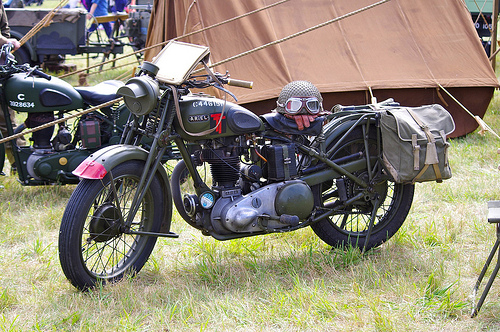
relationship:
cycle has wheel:
[50, 41, 451, 297] [64, 151, 163, 289]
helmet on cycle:
[268, 80, 322, 114] [50, 41, 451, 297]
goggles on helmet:
[282, 89, 321, 116] [268, 80, 322, 114]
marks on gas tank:
[212, 112, 231, 134] [186, 97, 252, 133]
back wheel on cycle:
[312, 120, 411, 252] [50, 41, 451, 297]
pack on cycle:
[382, 108, 452, 181] [50, 41, 451, 297]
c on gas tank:
[191, 101, 198, 110] [186, 97, 252, 133]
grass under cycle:
[156, 254, 326, 331] [50, 41, 451, 297]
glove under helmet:
[291, 114, 317, 124] [268, 80, 322, 114]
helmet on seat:
[268, 80, 322, 114] [263, 116, 322, 136]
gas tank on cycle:
[186, 97, 252, 133] [50, 41, 451, 297]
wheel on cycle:
[64, 151, 163, 289] [50, 41, 451, 297]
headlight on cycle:
[122, 79, 154, 115] [50, 41, 451, 297]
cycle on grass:
[50, 41, 451, 297] [156, 254, 326, 331]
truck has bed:
[2, 10, 130, 74] [41, 12, 115, 62]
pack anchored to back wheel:
[382, 108, 452, 181] [312, 120, 411, 252]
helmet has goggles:
[268, 80, 322, 114] [282, 89, 321, 116]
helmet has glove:
[268, 80, 322, 114] [291, 114, 317, 124]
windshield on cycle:
[147, 42, 203, 89] [50, 41, 451, 297]